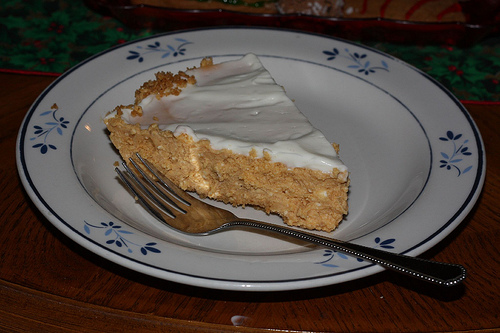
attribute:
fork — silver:
[116, 152, 465, 288]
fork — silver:
[88, 81, 473, 320]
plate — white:
[269, 32, 498, 247]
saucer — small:
[10, 21, 488, 294]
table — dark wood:
[3, 57, 498, 330]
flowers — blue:
[35, 29, 472, 270]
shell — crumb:
[118, 72, 208, 108]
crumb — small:
[43, 96, 60, 108]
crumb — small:
[111, 155, 127, 177]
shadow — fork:
[380, 276, 467, 303]